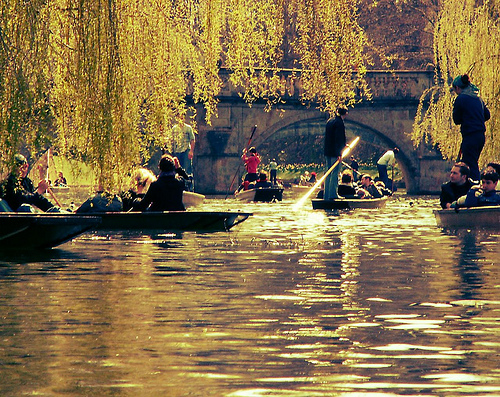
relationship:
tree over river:
[59, 17, 399, 139] [105, 196, 472, 393]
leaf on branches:
[85, 202, 94, 207] [204, 0, 280, 95]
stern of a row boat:
[227, 178, 291, 205] [226, 177, 286, 202]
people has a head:
[437, 162, 476, 209] [448, 157, 471, 185]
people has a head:
[437, 162, 476, 209] [446, 160, 467, 184]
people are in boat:
[446, 165, 482, 196] [437, 209, 484, 224]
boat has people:
[437, 209, 484, 224] [446, 165, 482, 196]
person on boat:
[481, 177, 483, 178] [438, 204, 483, 229]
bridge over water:
[182, 64, 438, 199] [264, 227, 444, 376]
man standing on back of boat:
[325, 108, 348, 203] [322, 187, 392, 209]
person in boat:
[241, 148, 260, 190] [240, 180, 287, 202]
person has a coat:
[241, 148, 260, 190] [240, 154, 262, 174]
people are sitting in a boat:
[437, 162, 476, 209] [434, 202, 484, 223]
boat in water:
[70, 211, 252, 231] [179, 255, 367, 356]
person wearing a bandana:
[450, 75, 488, 174] [450, 74, 475, 92]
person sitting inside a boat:
[129, 157, 195, 211] [70, 211, 252, 231]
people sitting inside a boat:
[3, 154, 65, 211] [0, 216, 103, 258]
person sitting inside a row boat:
[241, 148, 260, 190] [242, 184, 282, 201]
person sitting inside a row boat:
[306, 170, 316, 185] [282, 166, 324, 205]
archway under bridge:
[225, 112, 417, 200] [132, 65, 497, 212]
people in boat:
[1, 143, 347, 213] [70, 211, 252, 231]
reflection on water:
[318, 210, 355, 343] [261, 205, 434, 379]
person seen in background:
[241, 148, 260, 190] [147, 1, 484, 205]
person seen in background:
[264, 155, 279, 186] [147, 1, 484, 205]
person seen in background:
[249, 171, 274, 188] [147, 1, 484, 205]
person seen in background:
[305, 169, 316, 184] [147, 1, 484, 205]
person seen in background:
[358, 172, 383, 196] [147, 1, 484, 205]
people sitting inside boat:
[3, 154, 65, 211] [0, 210, 103, 257]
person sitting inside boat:
[129, 150, 187, 210] [65, 208, 254, 233]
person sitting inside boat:
[246, 171, 273, 188] [230, 186, 285, 202]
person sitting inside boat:
[358, 172, 383, 196] [309, 191, 389, 210]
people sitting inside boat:
[437, 162, 476, 209] [431, 203, 484, 228]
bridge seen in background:
[182, 64, 438, 199] [147, 1, 484, 205]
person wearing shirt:
[241, 148, 260, 190] [241, 154, 260, 174]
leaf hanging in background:
[85, 202, 94, 207] [1, 1, 483, 213]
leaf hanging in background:
[47, 32, 52, 38] [1, 1, 483, 213]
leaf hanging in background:
[179, 6, 182, 10] [1, 1, 483, 213]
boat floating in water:
[70, 209, 254, 231] [0, 185, 484, 391]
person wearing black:
[449, 72, 485, 181] [450, 90, 485, 180]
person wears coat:
[237, 140, 264, 187] [244, 154, 258, 172]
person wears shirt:
[375, 144, 396, 180] [377, 151, 395, 169]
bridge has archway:
[186, 64, 447, 180] [208, 104, 402, 178]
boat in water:
[4, 207, 104, 259] [6, 204, 198, 378]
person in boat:
[357, 171, 382, 196] [309, 191, 389, 210]